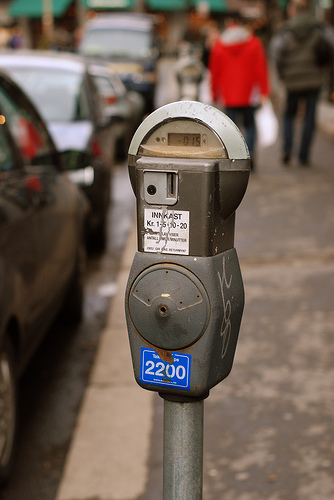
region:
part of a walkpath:
[274, 248, 309, 289]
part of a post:
[173, 441, 194, 467]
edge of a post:
[159, 456, 173, 485]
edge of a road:
[60, 401, 85, 441]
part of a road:
[38, 399, 72, 446]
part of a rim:
[0, 418, 22, 442]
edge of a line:
[73, 387, 100, 424]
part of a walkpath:
[248, 439, 288, 487]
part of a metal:
[210, 114, 258, 139]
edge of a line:
[57, 412, 86, 452]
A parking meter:
[71, 78, 289, 446]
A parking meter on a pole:
[86, 93, 284, 463]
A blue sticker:
[117, 331, 218, 403]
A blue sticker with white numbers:
[111, 340, 207, 405]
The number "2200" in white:
[138, 352, 191, 379]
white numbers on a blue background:
[116, 344, 222, 408]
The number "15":
[152, 112, 226, 169]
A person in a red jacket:
[196, 8, 274, 137]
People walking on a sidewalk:
[200, 6, 325, 208]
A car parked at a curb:
[17, 150, 130, 408]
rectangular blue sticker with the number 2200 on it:
[138, 345, 194, 397]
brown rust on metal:
[138, 329, 179, 368]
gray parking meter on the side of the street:
[109, 107, 255, 498]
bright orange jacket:
[203, 34, 271, 107]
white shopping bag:
[257, 95, 277, 150]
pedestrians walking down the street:
[204, 0, 332, 177]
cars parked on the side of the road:
[2, 11, 153, 473]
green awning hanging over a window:
[10, 2, 67, 18]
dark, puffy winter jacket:
[271, 16, 332, 99]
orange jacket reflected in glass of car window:
[11, 114, 42, 191]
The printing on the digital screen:
[175, 134, 202, 146]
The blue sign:
[137, 347, 193, 391]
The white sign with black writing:
[140, 207, 190, 258]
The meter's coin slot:
[168, 172, 176, 197]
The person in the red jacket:
[206, 13, 279, 174]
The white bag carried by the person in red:
[251, 93, 282, 151]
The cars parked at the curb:
[0, 9, 162, 496]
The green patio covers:
[7, 0, 306, 20]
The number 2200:
[143, 361, 184, 381]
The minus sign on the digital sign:
[174, 136, 183, 144]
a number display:
[165, 129, 201, 148]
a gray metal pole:
[160, 397, 208, 498]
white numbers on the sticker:
[143, 357, 185, 378]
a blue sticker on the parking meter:
[138, 344, 192, 388]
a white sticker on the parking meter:
[139, 206, 191, 255]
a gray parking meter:
[122, 98, 252, 403]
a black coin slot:
[167, 172, 179, 196]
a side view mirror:
[58, 145, 94, 175]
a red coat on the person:
[206, 24, 275, 108]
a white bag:
[245, 89, 281, 151]